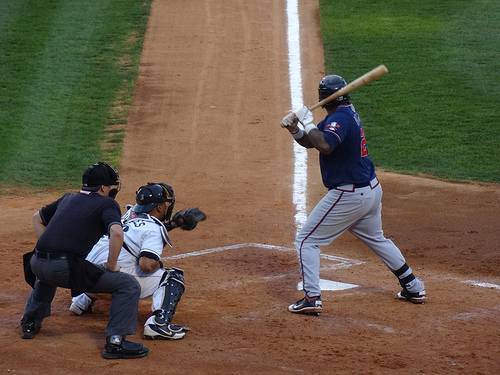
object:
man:
[19, 162, 148, 360]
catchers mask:
[132, 182, 176, 221]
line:
[285, 0, 308, 238]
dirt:
[153, 1, 488, 356]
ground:
[413, 139, 417, 148]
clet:
[288, 296, 323, 314]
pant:
[294, 177, 425, 297]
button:
[361, 193, 364, 195]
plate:
[160, 243, 366, 289]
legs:
[293, 203, 425, 297]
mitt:
[172, 207, 206, 231]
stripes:
[299, 189, 345, 292]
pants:
[21, 249, 139, 337]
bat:
[280, 63, 389, 128]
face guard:
[108, 188, 121, 199]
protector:
[151, 268, 186, 326]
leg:
[116, 266, 185, 323]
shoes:
[102, 340, 148, 360]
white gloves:
[293, 106, 317, 135]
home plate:
[297, 278, 359, 290]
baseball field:
[0, 0, 500, 258]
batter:
[279, 74, 426, 314]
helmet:
[318, 74, 351, 102]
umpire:
[20, 162, 150, 361]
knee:
[111, 277, 142, 296]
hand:
[101, 262, 122, 272]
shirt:
[317, 102, 377, 190]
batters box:
[160, 242, 500, 372]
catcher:
[68, 182, 207, 341]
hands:
[282, 105, 312, 129]